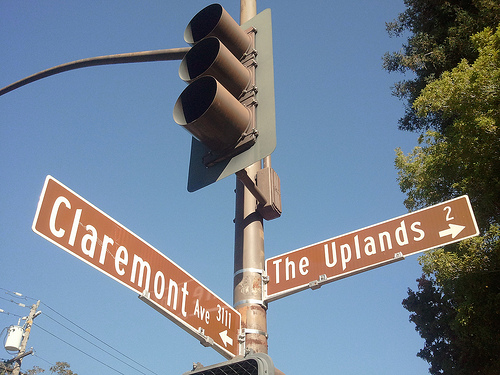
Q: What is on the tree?
A: There are green leaves on the tree.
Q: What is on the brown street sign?
A: There are white letters on the brown sign.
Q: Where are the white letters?
A: The white letters are on the brown sign.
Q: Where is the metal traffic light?
A: The metal traffic light is attached to a light pole.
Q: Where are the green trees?
A: The green trees are near the intersection.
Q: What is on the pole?
A: There are two street signs on the pole.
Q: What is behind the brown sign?
A: There is a blue sky behind the brown sign.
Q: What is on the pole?
A: The traffic lights are on the poles.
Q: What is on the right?
A: THe tall green tree is on the right.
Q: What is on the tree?
A: Leaves.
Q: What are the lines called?
A: Power lines.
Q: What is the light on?
A: Pole.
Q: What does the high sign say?
A: The uplands.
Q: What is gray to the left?
A: Transformer.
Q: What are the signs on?
A: Pole.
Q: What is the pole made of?
A: Metal.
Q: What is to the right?
A: Trees.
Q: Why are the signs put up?
A: Direction.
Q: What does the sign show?
A: Uplands street.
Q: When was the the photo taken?
A: Daylight.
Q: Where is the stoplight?
A: Intersection.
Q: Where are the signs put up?
A: Pole.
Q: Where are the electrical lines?
A: Far left.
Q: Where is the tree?
A: Far right.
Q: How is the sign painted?
A: Brown.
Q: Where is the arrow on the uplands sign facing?
A: Right.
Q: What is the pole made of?
A: Metal.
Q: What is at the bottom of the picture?
A: Street signs.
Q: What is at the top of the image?
A: Street lights.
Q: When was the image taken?
A: During the day.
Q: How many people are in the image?
A: Zero.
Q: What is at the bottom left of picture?
A: Power line.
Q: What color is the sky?
A: Blue.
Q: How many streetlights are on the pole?
A: Three.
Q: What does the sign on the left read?
A: Claremont Ave 3111.